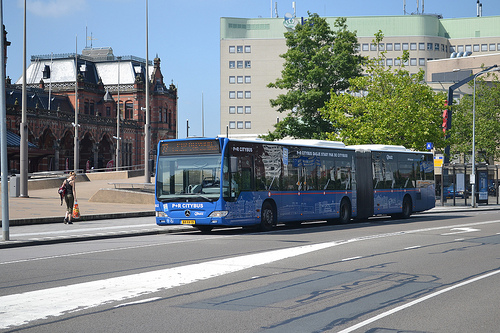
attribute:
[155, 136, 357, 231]
bus — blue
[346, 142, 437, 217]
bus — blue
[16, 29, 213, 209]
building — red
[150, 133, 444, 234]
bus — city, stop, long, blue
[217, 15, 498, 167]
building — large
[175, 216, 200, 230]
license plate — yellow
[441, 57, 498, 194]
lamppost — tall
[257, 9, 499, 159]
trees — green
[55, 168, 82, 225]
person — walking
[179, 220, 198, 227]
license plate — yellow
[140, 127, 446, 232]
bus — commuter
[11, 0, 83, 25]
cloud — thin, white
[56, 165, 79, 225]
bag — large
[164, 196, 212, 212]
letters — white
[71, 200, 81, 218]
bag — orange